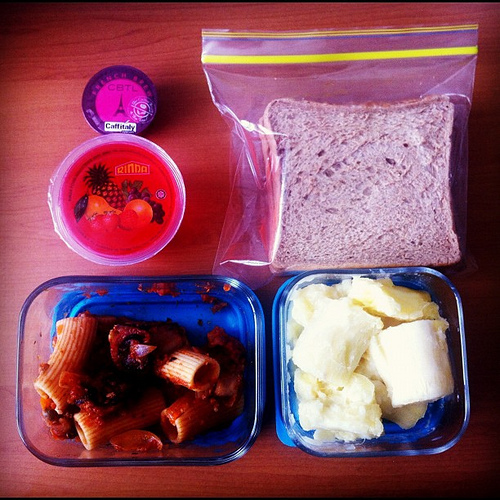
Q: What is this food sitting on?
A: Table.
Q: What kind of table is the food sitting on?
A: Wooden table.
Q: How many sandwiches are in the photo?
A: One.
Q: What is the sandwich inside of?
A: Plastic bag.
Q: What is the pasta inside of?
A: Glass bowl.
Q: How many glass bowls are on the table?
A: Two.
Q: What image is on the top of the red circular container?
A: Fruits.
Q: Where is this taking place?
A: In someone's house.